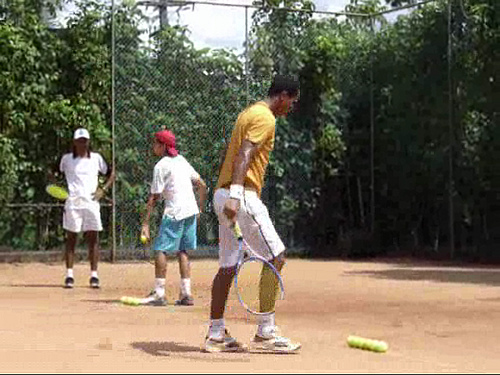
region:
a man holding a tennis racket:
[220, 77, 315, 321]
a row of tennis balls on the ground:
[341, 336, 393, 355]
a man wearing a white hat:
[71, 120, 91, 145]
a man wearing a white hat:
[153, 125, 184, 160]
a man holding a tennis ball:
[131, 139, 187, 269]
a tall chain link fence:
[288, 15, 358, 273]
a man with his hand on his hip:
[78, 149, 117, 214]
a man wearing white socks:
[148, 271, 200, 309]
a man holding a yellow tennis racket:
[53, 143, 92, 236]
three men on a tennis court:
[33, 67, 335, 308]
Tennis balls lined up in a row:
[333, 317, 394, 359]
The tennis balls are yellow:
[333, 330, 407, 357]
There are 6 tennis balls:
[341, 322, 400, 357]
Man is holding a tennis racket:
[206, 203, 291, 328]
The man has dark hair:
[255, 55, 317, 120]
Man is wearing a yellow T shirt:
[211, 90, 298, 200]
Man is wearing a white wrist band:
[217, 175, 252, 207]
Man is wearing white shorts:
[205, 176, 292, 257]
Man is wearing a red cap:
[130, 125, 185, 156]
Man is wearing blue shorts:
[132, 210, 203, 268]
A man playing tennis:
[210, 69, 315, 362]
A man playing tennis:
[147, 129, 201, 300]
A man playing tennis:
[49, 121, 119, 298]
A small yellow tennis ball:
[377, 341, 388, 350]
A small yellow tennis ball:
[367, 339, 374, 347]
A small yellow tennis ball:
[341, 335, 351, 344]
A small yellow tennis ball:
[135, 234, 153, 246]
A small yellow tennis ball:
[135, 301, 140, 309]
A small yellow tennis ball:
[118, 294, 125, 303]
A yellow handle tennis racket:
[223, 206, 283, 315]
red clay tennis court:
[81, 318, 185, 334]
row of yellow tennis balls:
[333, 324, 410, 369]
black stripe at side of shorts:
[241, 190, 288, 256]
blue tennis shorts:
[150, 206, 205, 270]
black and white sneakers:
[57, 268, 118, 295]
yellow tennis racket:
[31, 173, 84, 217]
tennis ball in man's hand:
[133, 227, 157, 244]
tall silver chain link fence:
[95, 8, 450, 121]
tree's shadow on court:
[345, 264, 482, 286]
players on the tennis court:
[54, 69, 338, 342]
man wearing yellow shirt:
[206, 66, 311, 353]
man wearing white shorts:
[210, 61, 300, 358]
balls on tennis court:
[330, 326, 400, 352]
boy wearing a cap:
[135, 117, 205, 312]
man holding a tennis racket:
[210, 60, 300, 360]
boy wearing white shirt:
[131, 115, 201, 315]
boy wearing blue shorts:
[110, 121, 195, 316]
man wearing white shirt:
[45, 112, 101, 302]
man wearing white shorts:
[30, 120, 107, 302]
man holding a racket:
[43, 124, 110, 298]